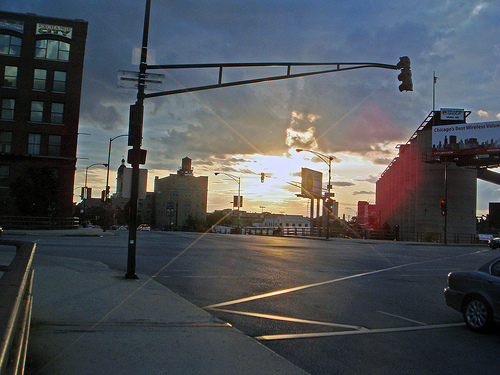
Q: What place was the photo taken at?
A: It was taken at the street.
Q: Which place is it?
A: It is a street.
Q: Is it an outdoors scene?
A: Yes, it is outdoors.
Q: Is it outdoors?
A: Yes, it is outdoors.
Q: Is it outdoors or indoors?
A: It is outdoors.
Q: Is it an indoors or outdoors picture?
A: It is outdoors.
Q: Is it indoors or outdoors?
A: It is outdoors.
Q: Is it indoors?
A: No, it is outdoors.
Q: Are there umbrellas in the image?
A: No, there are no umbrellas.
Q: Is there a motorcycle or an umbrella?
A: No, there are no umbrellas or motorcycles.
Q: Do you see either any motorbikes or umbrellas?
A: No, there are no umbrellas or motorbikes.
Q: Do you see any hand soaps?
A: No, there are no hand soaps.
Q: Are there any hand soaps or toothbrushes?
A: No, there are no hand soaps or toothbrushes.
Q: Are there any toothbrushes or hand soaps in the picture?
A: No, there are no hand soaps or toothbrushes.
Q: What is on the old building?
A: The pole is on the building.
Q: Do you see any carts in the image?
A: No, there are no carts.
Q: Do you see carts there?
A: No, there are no carts.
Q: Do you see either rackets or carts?
A: No, there are no carts or rackets.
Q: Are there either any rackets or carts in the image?
A: No, there are no carts or rackets.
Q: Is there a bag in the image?
A: No, there are no bags.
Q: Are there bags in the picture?
A: No, there are no bags.